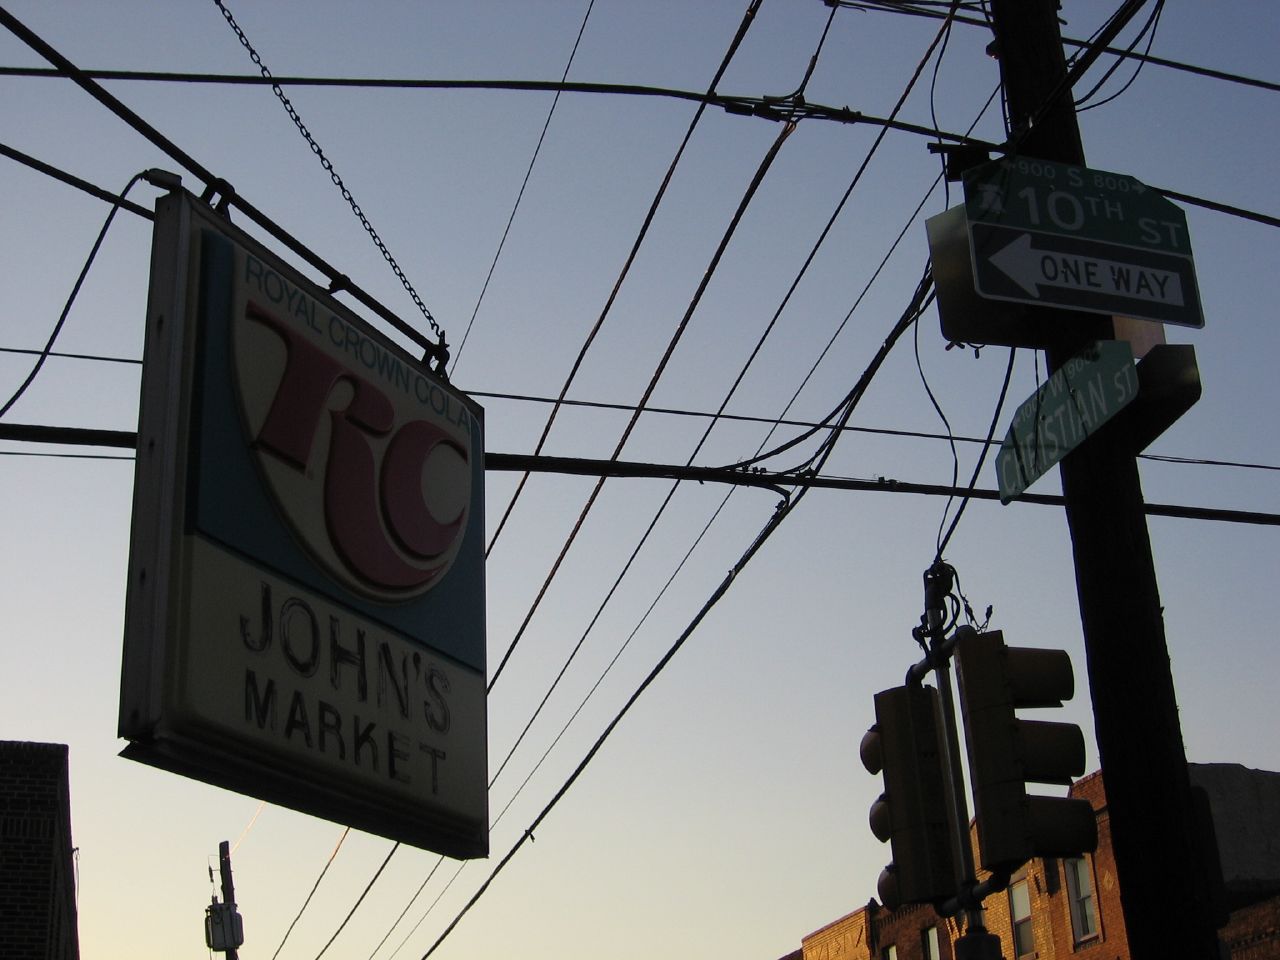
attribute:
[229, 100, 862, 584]
cables — suspended , utility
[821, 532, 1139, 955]
traffic signal — suspended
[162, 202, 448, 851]
sign — white, red, blue, business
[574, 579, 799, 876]
sky — clear, blue